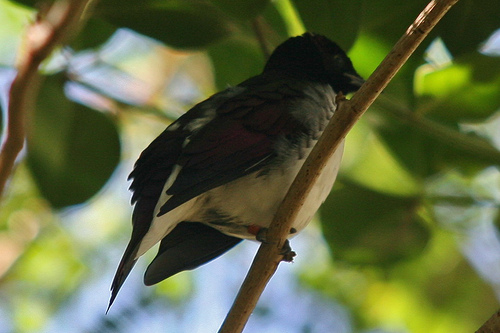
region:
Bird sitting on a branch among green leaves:
[4, 4, 495, 329]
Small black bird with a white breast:
[103, 33, 366, 306]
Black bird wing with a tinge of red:
[157, 88, 301, 218]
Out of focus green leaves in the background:
[1, 14, 497, 329]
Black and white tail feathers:
[104, 211, 156, 309]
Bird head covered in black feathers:
[267, 30, 366, 90]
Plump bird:
[103, 29, 368, 319]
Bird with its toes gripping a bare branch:
[106, 30, 366, 315]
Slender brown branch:
[217, 13, 454, 329]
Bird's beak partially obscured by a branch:
[344, 71, 376, 90]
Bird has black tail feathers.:
[95, 188, 145, 310]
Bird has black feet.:
[245, 223, 297, 287]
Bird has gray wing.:
[181, 118, 294, 173]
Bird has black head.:
[282, 33, 325, 78]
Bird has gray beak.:
[354, 70, 371, 88]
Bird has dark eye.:
[323, 50, 351, 69]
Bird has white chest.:
[300, 150, 347, 205]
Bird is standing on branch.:
[221, 178, 321, 308]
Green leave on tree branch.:
[35, 90, 131, 195]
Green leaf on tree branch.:
[430, 55, 485, 137]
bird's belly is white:
[241, 148, 329, 242]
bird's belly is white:
[301, 176, 322, 218]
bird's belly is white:
[225, 192, 295, 234]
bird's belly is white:
[295, 164, 330, 219]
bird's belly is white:
[311, 163, 338, 199]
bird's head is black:
[276, 33, 344, 78]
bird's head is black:
[245, 38, 309, 60]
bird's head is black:
[297, 28, 367, 105]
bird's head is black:
[256, 18, 316, 88]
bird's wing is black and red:
[181, 86, 288, 208]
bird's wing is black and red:
[188, 128, 291, 177]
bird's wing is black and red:
[218, 94, 283, 156]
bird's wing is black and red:
[229, 92, 264, 127]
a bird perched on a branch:
[94, 9, 339, 328]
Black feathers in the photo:
[215, 82, 290, 148]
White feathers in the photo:
[241, 179, 277, 209]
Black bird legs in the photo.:
[268, 236, 294, 263]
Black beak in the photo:
[332, 71, 367, 86]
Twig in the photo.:
[225, 215, 276, 330]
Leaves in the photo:
[360, 229, 462, 327]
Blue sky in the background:
[174, 267, 234, 310]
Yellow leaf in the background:
[7, 227, 77, 316]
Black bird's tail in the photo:
[107, 249, 141, 306]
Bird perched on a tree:
[107, 29, 376, 274]